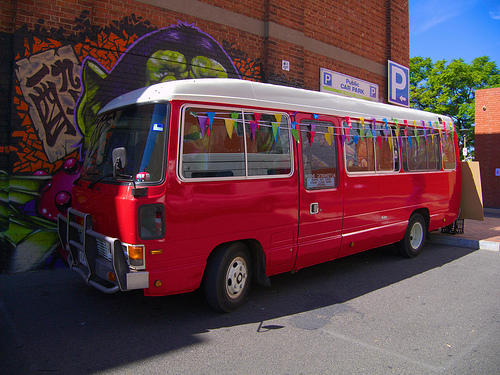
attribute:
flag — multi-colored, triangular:
[196, 114, 206, 136]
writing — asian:
[7, 40, 94, 157]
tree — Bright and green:
[405, 53, 498, 126]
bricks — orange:
[332, 17, 382, 49]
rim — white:
[226, 264, 247, 289]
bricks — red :
[215, 0, 407, 73]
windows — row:
[175, 108, 288, 174]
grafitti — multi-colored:
[1, 8, 288, 273]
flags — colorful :
[175, 96, 461, 172]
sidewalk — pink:
[432, 215, 499, 250]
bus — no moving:
[49, 62, 469, 264]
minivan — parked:
[63, 78, 462, 313]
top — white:
[94, 64, 465, 132]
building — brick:
[230, 50, 321, 80]